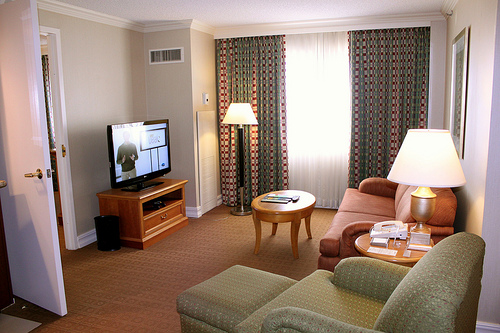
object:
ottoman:
[177, 262, 298, 333]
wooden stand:
[95, 177, 188, 251]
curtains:
[344, 26, 430, 190]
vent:
[147, 47, 183, 65]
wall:
[140, 27, 197, 207]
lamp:
[385, 127, 467, 253]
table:
[353, 232, 437, 268]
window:
[212, 27, 435, 209]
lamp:
[219, 101, 259, 217]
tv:
[106, 117, 173, 194]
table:
[249, 188, 317, 260]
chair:
[172, 230, 485, 333]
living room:
[0, 0, 499, 332]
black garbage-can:
[91, 213, 123, 252]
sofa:
[318, 177, 457, 275]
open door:
[2, 0, 71, 315]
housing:
[104, 118, 171, 189]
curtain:
[215, 34, 289, 208]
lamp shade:
[386, 126, 467, 189]